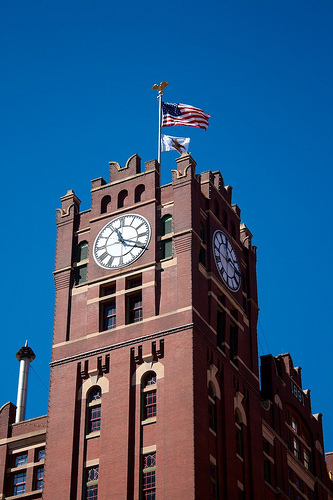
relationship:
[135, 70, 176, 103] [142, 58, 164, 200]
eagle on pole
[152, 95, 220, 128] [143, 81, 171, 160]
flag on a pole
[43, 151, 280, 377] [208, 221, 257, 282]
tower has clock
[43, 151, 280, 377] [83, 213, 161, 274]
tower has clock